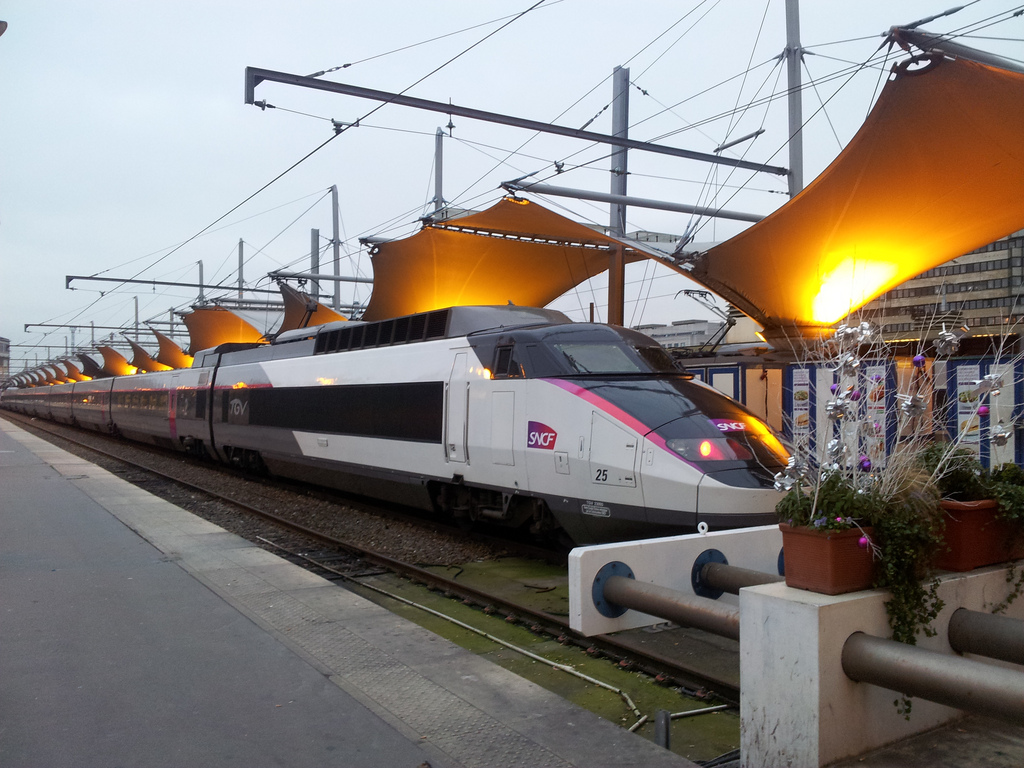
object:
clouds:
[0, 0, 1024, 386]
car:
[0, 302, 832, 551]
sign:
[526, 419, 556, 450]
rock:
[269, 508, 282, 516]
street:
[0, 417, 740, 766]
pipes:
[840, 629, 1023, 716]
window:
[488, 323, 680, 382]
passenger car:
[107, 366, 217, 457]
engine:
[210, 301, 815, 555]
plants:
[775, 312, 1024, 721]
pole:
[607, 56, 631, 345]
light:
[696, 438, 728, 462]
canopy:
[0, 158, 654, 388]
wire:
[0, 0, 1024, 389]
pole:
[772, 0, 808, 540]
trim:
[517, 318, 772, 498]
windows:
[47, 388, 209, 423]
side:
[210, 379, 445, 443]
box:
[778, 518, 873, 596]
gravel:
[298, 551, 311, 557]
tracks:
[3, 412, 739, 703]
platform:
[0, 406, 740, 768]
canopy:
[2, 56, 1023, 412]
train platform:
[0, 390, 703, 765]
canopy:
[142, 276, 329, 375]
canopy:
[65, 336, 137, 379]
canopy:
[91, 343, 148, 384]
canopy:
[58, 347, 130, 388]